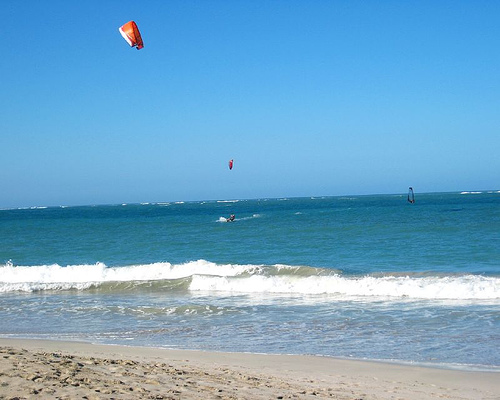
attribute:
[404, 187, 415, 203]
vessel — recreational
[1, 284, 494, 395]
beach — sandy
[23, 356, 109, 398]
sand — brown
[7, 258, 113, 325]
water — splashing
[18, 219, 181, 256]
water — blue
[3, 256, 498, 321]
waves — cresting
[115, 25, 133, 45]
stripe — white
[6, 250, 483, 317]
waves — are white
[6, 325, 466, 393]
beach — are white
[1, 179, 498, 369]
water — glue, green, grey, foamy, turquoise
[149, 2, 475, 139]
sky — blue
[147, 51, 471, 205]
sky — blue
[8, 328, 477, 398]
beach — sandy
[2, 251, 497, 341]
waves — white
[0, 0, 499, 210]
sky — blue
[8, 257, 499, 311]
waves — white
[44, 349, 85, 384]
sand — brown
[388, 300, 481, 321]
water — shallow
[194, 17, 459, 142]
blue sky — cloudless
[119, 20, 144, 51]
kite — red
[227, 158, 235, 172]
kite — red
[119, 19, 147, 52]
parasail — open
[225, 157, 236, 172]
parasail — open